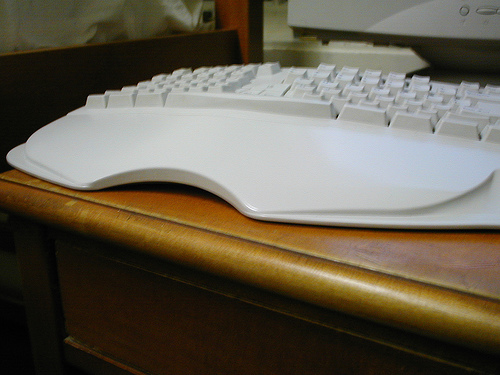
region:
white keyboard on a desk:
[4, 41, 499, 236]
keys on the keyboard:
[86, 52, 499, 144]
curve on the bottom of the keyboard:
[84, 161, 259, 216]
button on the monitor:
[457, 4, 472, 17]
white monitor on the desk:
[269, 3, 497, 79]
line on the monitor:
[362, 0, 419, 32]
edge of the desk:
[4, 181, 496, 373]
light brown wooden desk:
[1, 164, 499, 366]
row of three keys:
[339, 101, 477, 149]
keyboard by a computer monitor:
[12, 1, 497, 234]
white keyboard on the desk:
[0, 35, 499, 250]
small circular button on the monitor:
[458, 2, 474, 17]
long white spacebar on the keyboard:
[167, 88, 336, 126]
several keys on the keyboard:
[75, 52, 499, 154]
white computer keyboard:
[119, 57, 498, 157]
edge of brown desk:
[0, 174, 114, 239]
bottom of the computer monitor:
[289, 0, 499, 50]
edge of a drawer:
[51, 231, 143, 360]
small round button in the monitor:
[454, 5, 474, 20]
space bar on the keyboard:
[163, 88, 335, 118]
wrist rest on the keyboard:
[63, 119, 488, 248]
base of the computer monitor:
[409, 51, 499, 82]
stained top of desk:
[376, 234, 492, 283]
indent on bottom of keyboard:
[76, 160, 269, 217]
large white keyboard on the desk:
[9, 44, 492, 259]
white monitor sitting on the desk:
[276, 0, 499, 60]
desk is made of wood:
[2, 138, 498, 374]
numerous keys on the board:
[73, 56, 496, 155]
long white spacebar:
[166, 88, 335, 125]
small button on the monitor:
[457, 4, 472, 19]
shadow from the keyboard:
[129, 181, 211, 203]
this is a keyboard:
[4, 48, 498, 234]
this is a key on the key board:
[345, 101, 385, 126]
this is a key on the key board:
[433, 110, 479, 146]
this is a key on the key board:
[172, 90, 344, 115]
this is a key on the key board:
[127, 85, 167, 109]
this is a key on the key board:
[104, 90, 135, 107]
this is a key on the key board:
[84, 92, 111, 105]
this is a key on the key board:
[364, 88, 401, 107]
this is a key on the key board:
[384, 60, 411, 87]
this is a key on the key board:
[309, 68, 331, 85]